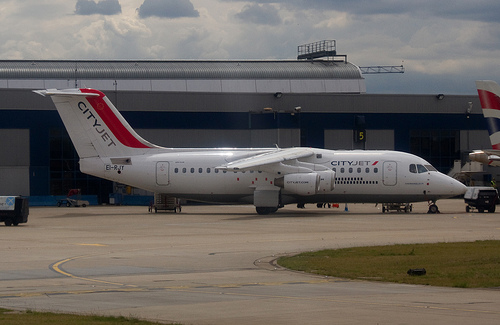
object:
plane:
[31, 86, 466, 216]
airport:
[0, 37, 499, 206]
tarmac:
[0, 196, 499, 325]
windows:
[174, 166, 179, 174]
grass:
[275, 234, 499, 289]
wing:
[214, 146, 322, 169]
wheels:
[428, 202, 440, 216]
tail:
[30, 87, 163, 155]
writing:
[76, 100, 120, 150]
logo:
[327, 160, 372, 168]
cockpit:
[404, 153, 442, 184]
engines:
[269, 170, 323, 196]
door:
[379, 159, 398, 187]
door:
[153, 160, 173, 187]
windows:
[406, 164, 418, 174]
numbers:
[120, 164, 126, 171]